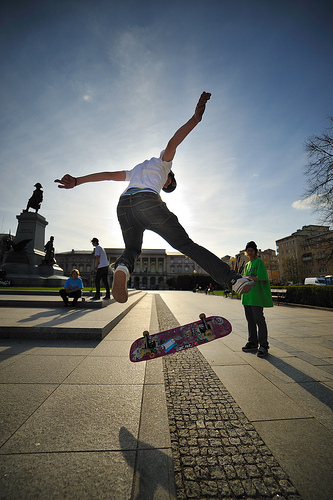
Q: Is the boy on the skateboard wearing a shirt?
A: Yes, the boy is wearing a shirt.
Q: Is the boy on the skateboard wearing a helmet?
A: No, the boy is wearing a shirt.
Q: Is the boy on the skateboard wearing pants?
A: Yes, the boy is wearing pants.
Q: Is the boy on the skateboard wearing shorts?
A: No, the boy is wearing pants.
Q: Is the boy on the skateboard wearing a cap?
A: Yes, the boy is wearing a cap.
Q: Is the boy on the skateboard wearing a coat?
A: No, the boy is wearing a cap.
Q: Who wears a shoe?
A: The boy wears a shoe.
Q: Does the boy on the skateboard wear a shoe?
A: Yes, the boy wears a shoe.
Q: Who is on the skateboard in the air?
A: The boy is on the skateboard.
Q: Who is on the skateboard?
A: The boy is on the skateboard.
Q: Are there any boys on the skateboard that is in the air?
A: Yes, there is a boy on the skateboard.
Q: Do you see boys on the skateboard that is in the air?
A: Yes, there is a boy on the skateboard.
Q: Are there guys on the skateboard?
A: No, there is a boy on the skateboard.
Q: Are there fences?
A: No, there are no fences.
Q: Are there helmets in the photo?
A: No, there are no helmets.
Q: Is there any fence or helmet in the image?
A: No, there are no helmets or fences.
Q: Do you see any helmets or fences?
A: No, there are no helmets or fences.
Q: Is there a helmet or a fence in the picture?
A: No, there are no fences or helmets.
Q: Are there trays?
A: No, there are no trays.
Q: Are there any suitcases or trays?
A: No, there are no trays or suitcases.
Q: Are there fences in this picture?
A: No, there are no fences.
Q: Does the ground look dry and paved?
A: Yes, the ground is dry and paved.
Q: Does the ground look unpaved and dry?
A: No, the ground is dry but paved.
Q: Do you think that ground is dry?
A: Yes, the ground is dry.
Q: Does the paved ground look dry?
A: Yes, the ground is dry.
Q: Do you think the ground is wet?
A: No, the ground is dry.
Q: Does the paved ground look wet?
A: No, the ground is dry.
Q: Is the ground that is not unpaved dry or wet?
A: The ground is dry.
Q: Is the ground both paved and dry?
A: Yes, the ground is paved and dry.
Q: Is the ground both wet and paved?
A: No, the ground is paved but dry.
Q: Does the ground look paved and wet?
A: No, the ground is paved but dry.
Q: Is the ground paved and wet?
A: No, the ground is paved but dry.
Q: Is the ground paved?
A: Yes, the ground is paved.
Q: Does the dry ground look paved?
A: Yes, the ground is paved.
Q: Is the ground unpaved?
A: No, the ground is paved.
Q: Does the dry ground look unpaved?
A: No, the ground is paved.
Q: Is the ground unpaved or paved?
A: The ground is paved.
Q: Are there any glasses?
A: No, there are no glasses.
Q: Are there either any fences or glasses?
A: No, there are no glasses or fences.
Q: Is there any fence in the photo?
A: No, there are no fences.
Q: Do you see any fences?
A: No, there are no fences.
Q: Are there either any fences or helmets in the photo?
A: No, there are no fences or helmets.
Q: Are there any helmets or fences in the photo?
A: No, there are no fences or helmets.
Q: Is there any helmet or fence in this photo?
A: No, there are no fences or helmets.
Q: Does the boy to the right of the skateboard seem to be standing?
A: Yes, the boy is standing.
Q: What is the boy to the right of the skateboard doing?
A: The boy is standing.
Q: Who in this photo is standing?
A: The boy is standing.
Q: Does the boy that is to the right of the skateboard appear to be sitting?
A: No, the boy is standing.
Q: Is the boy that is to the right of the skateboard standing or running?
A: The boy is standing.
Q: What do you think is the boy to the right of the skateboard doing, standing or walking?
A: The boy is standing.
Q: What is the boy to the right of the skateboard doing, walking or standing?
A: The boy is standing.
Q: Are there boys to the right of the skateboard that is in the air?
A: Yes, there is a boy to the right of the skateboard.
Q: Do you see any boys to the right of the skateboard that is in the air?
A: Yes, there is a boy to the right of the skateboard.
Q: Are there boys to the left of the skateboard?
A: No, the boy is to the right of the skateboard.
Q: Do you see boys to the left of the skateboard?
A: No, the boy is to the right of the skateboard.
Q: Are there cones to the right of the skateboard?
A: No, there is a boy to the right of the skateboard.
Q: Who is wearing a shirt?
A: The boy is wearing a shirt.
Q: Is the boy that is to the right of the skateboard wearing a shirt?
A: Yes, the boy is wearing a shirt.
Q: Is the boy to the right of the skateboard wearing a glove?
A: No, the boy is wearing a shirt.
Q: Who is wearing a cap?
A: The boy is wearing a cap.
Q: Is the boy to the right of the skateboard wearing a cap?
A: Yes, the boy is wearing a cap.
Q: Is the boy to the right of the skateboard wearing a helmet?
A: No, the boy is wearing a cap.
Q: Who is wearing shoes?
A: The boy is wearing shoes.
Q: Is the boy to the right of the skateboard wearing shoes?
A: Yes, the boy is wearing shoes.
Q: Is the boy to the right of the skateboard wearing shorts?
A: No, the boy is wearing shoes.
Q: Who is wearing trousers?
A: The boy is wearing trousers.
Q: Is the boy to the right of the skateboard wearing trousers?
A: Yes, the boy is wearing trousers.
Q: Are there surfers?
A: No, there are no surfers.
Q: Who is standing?
A: The boy is standing.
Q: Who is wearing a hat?
A: The boy is wearing a hat.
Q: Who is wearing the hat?
A: The boy is wearing a hat.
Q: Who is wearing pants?
A: The boy is wearing pants.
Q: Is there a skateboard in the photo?
A: Yes, there is a skateboard.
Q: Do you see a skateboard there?
A: Yes, there is a skateboard.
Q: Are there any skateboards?
A: Yes, there is a skateboard.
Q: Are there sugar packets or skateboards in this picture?
A: Yes, there is a skateboard.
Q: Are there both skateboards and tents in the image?
A: No, there is a skateboard but no tents.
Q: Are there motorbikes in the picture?
A: No, there are no motorbikes.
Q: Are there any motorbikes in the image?
A: No, there are no motorbikes.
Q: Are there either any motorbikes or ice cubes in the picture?
A: No, there are no motorbikes or ice cubes.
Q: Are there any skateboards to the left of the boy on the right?
A: Yes, there is a skateboard to the left of the boy.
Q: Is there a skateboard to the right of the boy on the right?
A: No, the skateboard is to the left of the boy.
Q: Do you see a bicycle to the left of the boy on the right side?
A: No, there is a skateboard to the left of the boy.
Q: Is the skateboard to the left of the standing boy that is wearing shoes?
A: Yes, the skateboard is to the left of the boy.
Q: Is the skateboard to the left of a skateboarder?
A: No, the skateboard is to the left of the boy.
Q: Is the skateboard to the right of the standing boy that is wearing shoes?
A: No, the skateboard is to the left of the boy.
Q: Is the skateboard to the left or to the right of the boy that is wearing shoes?
A: The skateboard is to the left of the boy.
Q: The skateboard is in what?
A: The skateboard is in the air.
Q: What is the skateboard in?
A: The skateboard is in the air.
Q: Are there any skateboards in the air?
A: Yes, there is a skateboard in the air.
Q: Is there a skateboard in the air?
A: Yes, there is a skateboard in the air.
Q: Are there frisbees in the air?
A: No, there is a skateboard in the air.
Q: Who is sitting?
A: The boy is sitting.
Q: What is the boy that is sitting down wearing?
A: The boy is wearing a shirt.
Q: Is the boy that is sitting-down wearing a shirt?
A: Yes, the boy is wearing a shirt.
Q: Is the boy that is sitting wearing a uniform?
A: No, the boy is wearing a shirt.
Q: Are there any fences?
A: No, there are no fences.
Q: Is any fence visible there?
A: No, there are no fences.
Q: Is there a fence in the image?
A: No, there are no fences.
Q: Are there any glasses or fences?
A: No, there are no fences or glasses.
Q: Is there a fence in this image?
A: No, there are no fences.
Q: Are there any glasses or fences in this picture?
A: No, there are no fences or glasses.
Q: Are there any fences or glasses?
A: No, there are no fences or glasses.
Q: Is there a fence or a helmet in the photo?
A: No, there are no fences or helmets.